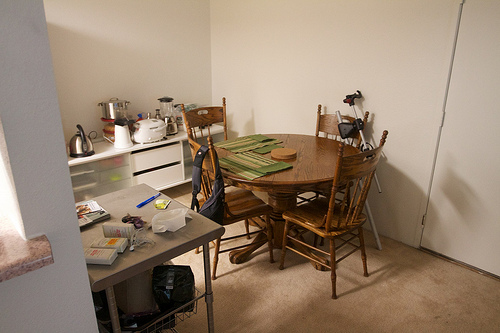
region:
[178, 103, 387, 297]
A wooden dining room set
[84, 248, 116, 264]
a white box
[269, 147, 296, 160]
A table decoration on a table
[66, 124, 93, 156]
A metal tea kettle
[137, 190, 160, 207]
A blue utencil on a table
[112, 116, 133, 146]
a white pitcher on a counter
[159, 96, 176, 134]
A metal blender on a counter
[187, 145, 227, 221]
A bag on a chair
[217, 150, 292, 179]
A green and yellow placemat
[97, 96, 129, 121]
A metal pan on a cabinet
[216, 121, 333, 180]
the table is round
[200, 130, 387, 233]
the chairs are wooden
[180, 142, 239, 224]
the bag is on the chair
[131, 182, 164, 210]
the blue pen is on the table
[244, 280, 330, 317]
the floor is carpeted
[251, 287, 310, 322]
the floor is brown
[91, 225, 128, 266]
containers are on the table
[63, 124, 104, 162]
kettle is on the cooker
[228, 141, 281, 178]
table mat is blue in color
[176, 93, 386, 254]
four chairs are around the table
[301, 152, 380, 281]
a wooden chair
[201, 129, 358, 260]
a wooden table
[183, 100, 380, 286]
a table and four chairs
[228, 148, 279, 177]
a green dinner placemat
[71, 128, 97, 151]
a silver kettle on the counter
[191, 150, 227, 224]
a bag on the chair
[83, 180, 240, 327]
a silver table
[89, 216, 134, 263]
books on the table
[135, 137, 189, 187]
drawers on the counter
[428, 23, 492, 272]
a white door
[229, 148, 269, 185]
a placemat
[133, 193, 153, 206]
a blue pen on the table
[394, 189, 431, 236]
a shadow on the wall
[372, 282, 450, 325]
the carpet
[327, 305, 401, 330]
the carpet is brown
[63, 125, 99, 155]
a coffee pot on the counter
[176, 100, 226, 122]
the chair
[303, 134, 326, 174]
the table is brown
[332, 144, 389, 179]
the chair is brown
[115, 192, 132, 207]
the counter is grey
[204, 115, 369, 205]
a brown wooden table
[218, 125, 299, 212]
placemates on the table